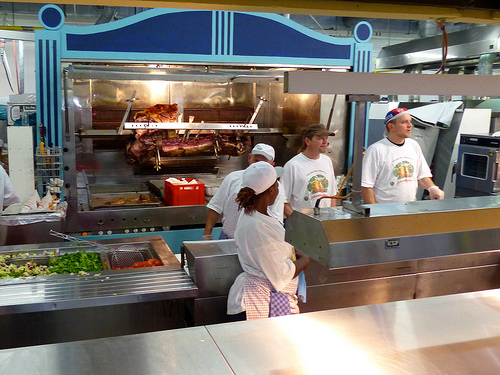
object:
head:
[383, 108, 414, 137]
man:
[360, 105, 445, 203]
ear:
[384, 122, 392, 132]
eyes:
[400, 120, 405, 126]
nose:
[406, 120, 414, 128]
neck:
[390, 140, 408, 147]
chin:
[401, 134, 413, 141]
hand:
[426, 187, 446, 199]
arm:
[357, 149, 373, 202]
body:
[202, 170, 287, 242]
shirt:
[359, 136, 434, 204]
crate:
[161, 177, 204, 206]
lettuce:
[47, 250, 103, 275]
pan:
[109, 245, 144, 270]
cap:
[299, 122, 335, 140]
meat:
[107, 197, 139, 204]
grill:
[90, 182, 145, 195]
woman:
[226, 160, 311, 322]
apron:
[240, 273, 298, 320]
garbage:
[0, 178, 68, 217]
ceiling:
[0, 0, 499, 53]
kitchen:
[0, 0, 499, 374]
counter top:
[283, 194, 499, 266]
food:
[123, 102, 248, 164]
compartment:
[167, 65, 254, 111]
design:
[388, 160, 414, 186]